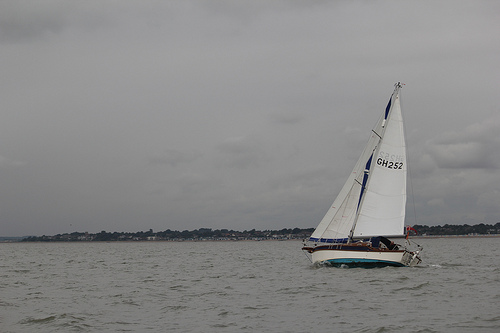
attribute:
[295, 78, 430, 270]
sail boat — moving, wooden, sailing, blue, turning, floating, large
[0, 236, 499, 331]
water — choppy, moving, gentle, grey, active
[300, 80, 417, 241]
sail — white, large, light, blue, pointy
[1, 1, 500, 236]
sky — dark, grey, cloudy, stormy, large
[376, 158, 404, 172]
writing — black, dark, small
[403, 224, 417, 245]
ribbon — red